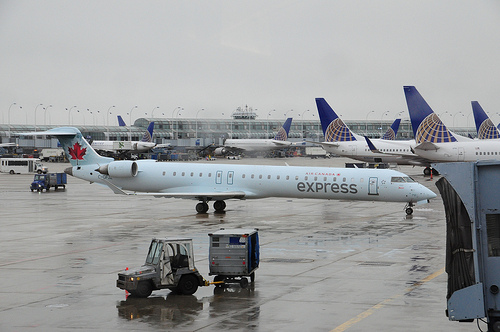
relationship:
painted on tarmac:
[316, 261, 450, 328] [1, 153, 484, 330]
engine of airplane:
[93, 155, 148, 181] [8, 122, 438, 218]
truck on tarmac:
[114, 221, 268, 301] [13, 198, 436, 322]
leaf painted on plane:
[59, 140, 89, 166] [26, 118, 114, 185]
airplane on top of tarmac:
[8, 122, 438, 218] [18, 115, 452, 330]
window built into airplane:
[284, 173, 291, 180] [8, 122, 438, 218]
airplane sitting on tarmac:
[8, 122, 438, 218] [1, 153, 484, 330]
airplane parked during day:
[8, 122, 438, 218] [1, 1, 484, 329]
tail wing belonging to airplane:
[7, 125, 117, 166] [8, 122, 438, 218]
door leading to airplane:
[214, 169, 223, 185] [8, 122, 438, 218]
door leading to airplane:
[225, 170, 233, 183] [8, 122, 438, 218]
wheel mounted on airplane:
[194, 200, 210, 213] [8, 122, 438, 218]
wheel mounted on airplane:
[211, 199, 227, 213] [8, 122, 438, 218]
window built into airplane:
[161, 170, 165, 175] [8, 122, 438, 218]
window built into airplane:
[171, 170, 177, 177] [8, 122, 438, 218]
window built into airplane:
[188, 170, 195, 177] [8, 122, 438, 218]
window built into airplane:
[240, 172, 246, 180] [8, 122, 438, 218]